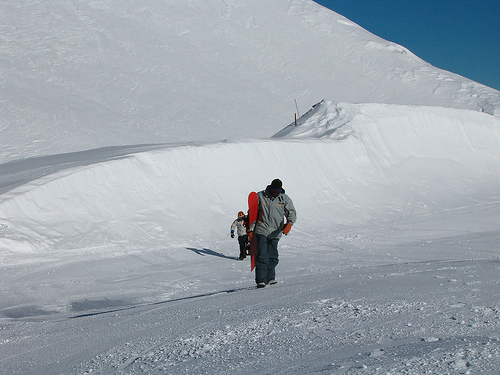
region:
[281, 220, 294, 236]
a man's red glove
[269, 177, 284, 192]
the head of a man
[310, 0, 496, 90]
a blue sky over the snow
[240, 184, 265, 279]
a red snowboard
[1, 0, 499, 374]
white snow on the ground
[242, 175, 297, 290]
a man holding a snowboard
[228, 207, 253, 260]
a man in the background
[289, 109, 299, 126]
a post in the snow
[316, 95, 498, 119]
a ridge of snow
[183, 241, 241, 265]
a shadow cast on the ground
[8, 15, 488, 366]
two snowboarders on a mountain of snow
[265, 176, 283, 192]
the snowboarder is wearing a black ski hat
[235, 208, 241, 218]
a snowboarder is wearing a red knit ski hat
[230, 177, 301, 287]
two snowboarders are walking in the snow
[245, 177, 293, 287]
the snowboarder is carrying a red snowboard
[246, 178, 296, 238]
the snowboarder is wearing a silver jacket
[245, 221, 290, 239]
the man has red ski gloves on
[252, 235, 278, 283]
the man is wearing black ski pants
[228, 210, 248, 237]
a man has a white ski jacket on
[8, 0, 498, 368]
A bright blue sky is in the background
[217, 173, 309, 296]
snowboarder walking up slope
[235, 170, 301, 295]
snowboarder carrying board under arm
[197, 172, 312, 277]
red snowboard and red gloves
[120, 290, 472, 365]
chunks of snow scattered across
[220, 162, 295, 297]
person walking behind snowboarder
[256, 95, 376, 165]
change in elevation on snow bank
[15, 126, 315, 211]
smooth curve of snow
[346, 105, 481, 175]
ridges along side of snow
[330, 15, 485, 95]
uneven and rough edge of slope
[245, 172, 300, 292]
outfit of grey jacket and black pants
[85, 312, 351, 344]
the snow is white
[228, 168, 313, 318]
there are two men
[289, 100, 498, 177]
the hill is made of snow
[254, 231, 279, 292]
the man's pants are gray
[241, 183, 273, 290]
the man is holding a snowboard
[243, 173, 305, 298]
the man is wearing a hat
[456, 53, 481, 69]
the sky is blue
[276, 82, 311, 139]
there's a stick in the snow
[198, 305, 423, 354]
the snow is course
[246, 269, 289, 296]
the man is wearing shoes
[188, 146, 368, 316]
Man is walking in the snow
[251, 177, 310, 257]
Man is wearing a gray coat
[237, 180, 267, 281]
Man has a red snowboard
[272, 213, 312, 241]
Man has orange gloves on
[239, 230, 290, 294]
Man is wearing dark colored pants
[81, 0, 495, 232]
A mountain of snow is behind the man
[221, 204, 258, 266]
A person is in the background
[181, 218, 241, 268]
Person in the background is casting a shadow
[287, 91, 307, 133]
A pole is in the background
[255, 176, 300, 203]
Man has his head looking down